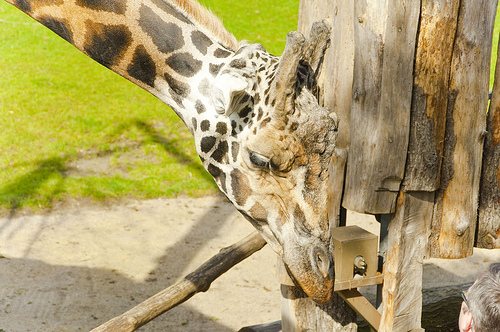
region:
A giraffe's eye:
[239, 121, 273, 179]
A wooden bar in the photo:
[158, 250, 240, 288]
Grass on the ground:
[25, 118, 165, 198]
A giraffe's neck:
[199, 39, 333, 302]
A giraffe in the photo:
[14, 0, 356, 297]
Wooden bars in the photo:
[363, 134, 478, 259]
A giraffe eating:
[137, 16, 344, 301]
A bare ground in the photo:
[90, 217, 188, 255]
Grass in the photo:
[5, 77, 100, 197]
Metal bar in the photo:
[324, 235, 389, 322]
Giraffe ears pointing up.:
[262, 15, 351, 120]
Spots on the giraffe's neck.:
[99, 14, 209, 96]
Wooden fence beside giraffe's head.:
[366, 5, 493, 262]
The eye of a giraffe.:
[246, 150, 274, 173]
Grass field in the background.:
[17, 61, 133, 182]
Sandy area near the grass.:
[23, 243, 159, 296]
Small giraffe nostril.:
[310, 248, 327, 275]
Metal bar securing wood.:
[336, 225, 393, 325]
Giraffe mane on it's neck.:
[189, 0, 243, 54]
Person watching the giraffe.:
[446, 255, 498, 330]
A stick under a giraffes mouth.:
[85, 229, 267, 330]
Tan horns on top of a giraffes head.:
[269, 20, 335, 109]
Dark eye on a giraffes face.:
[242, 148, 272, 169]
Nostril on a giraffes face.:
[316, 249, 331, 274]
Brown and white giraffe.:
[0, 2, 340, 299]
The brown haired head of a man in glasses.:
[460, 261, 498, 330]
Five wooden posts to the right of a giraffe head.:
[303, 0, 497, 255]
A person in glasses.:
[458, 259, 499, 330]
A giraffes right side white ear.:
[213, 74, 248, 116]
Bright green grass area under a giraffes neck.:
[2, 3, 222, 202]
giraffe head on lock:
[230, 23, 386, 292]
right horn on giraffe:
[267, 28, 308, 141]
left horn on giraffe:
[305, 15, 334, 93]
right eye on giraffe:
[250, 146, 272, 177]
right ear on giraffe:
[219, 47, 261, 128]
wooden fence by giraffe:
[357, 12, 495, 218]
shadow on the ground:
[11, 115, 63, 259]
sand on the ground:
[41, 227, 142, 288]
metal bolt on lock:
[352, 248, 374, 277]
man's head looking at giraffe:
[447, 266, 498, 325]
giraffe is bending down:
[51, 3, 416, 328]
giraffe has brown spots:
[124, 0, 199, 57]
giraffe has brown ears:
[270, 13, 345, 134]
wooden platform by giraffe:
[337, 18, 494, 300]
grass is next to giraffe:
[8, 45, 190, 205]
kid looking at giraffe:
[434, 245, 499, 327]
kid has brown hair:
[440, 262, 498, 325]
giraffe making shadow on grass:
[17, 100, 231, 318]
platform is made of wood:
[344, 19, 476, 271]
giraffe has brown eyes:
[231, 139, 296, 177]